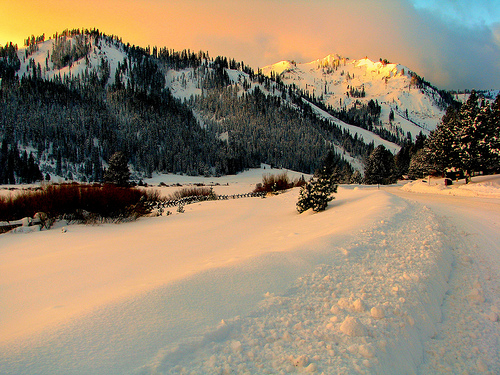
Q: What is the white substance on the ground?
A: Snow.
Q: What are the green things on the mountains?
A: Trees.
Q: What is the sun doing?
A: Rising or setting.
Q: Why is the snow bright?
A: Reflecting sun.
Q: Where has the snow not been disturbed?
A: To the left.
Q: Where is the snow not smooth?
A: To the right.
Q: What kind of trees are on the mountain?
A: Evergreens.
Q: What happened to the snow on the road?
A: Plowed.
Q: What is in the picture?
A: Mountain.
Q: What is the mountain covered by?
A: Snow.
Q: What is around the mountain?
A: Trees.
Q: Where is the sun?
A: Above the mountains.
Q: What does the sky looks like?
A: Blue.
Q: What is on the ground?
A: Snow.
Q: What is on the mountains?
A: Snow.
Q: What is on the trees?
A: Snow.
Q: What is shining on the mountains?
A: The sun.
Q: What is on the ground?
A: A pathway.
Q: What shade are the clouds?
A: Orange.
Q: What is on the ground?
A: Snow.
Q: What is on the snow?
A: Clumps of snow.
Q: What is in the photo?
A: Hills.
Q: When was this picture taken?
A: Day time.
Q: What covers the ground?
A: Snow.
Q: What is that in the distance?
A: Mountains.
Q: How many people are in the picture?
A: None.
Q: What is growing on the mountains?
A: Trees.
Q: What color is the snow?
A: White.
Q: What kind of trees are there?
A: Pine trees.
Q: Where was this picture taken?
A: Mountain.